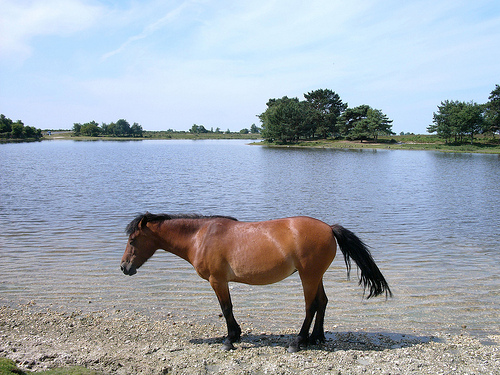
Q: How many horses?
A: 1.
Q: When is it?
A: Day time.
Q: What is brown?
A: The horse.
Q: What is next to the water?
A: Trees.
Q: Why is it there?
A: To drink.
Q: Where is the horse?
A: Near the water.